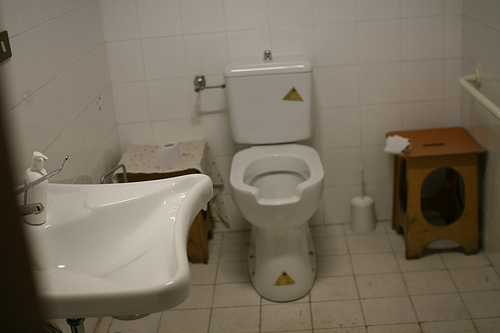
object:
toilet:
[223, 54, 326, 304]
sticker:
[281, 88, 302, 103]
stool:
[385, 127, 489, 261]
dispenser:
[23, 201, 47, 227]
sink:
[14, 173, 215, 319]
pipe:
[193, 75, 226, 93]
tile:
[312, 65, 361, 109]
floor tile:
[353, 271, 411, 299]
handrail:
[458, 73, 500, 120]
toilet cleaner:
[351, 165, 377, 236]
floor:
[89, 219, 500, 333]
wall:
[0, 0, 121, 183]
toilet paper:
[156, 140, 182, 171]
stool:
[115, 142, 213, 265]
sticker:
[274, 272, 295, 287]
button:
[263, 49, 272, 62]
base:
[244, 222, 318, 303]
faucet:
[26, 150, 48, 170]